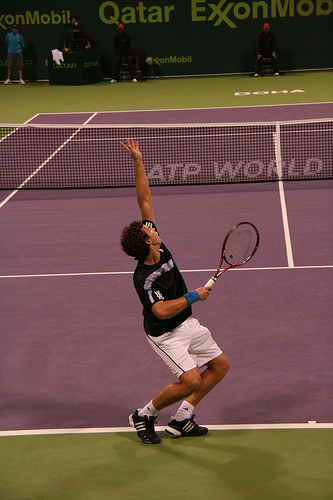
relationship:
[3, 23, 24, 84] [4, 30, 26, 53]
man in shirt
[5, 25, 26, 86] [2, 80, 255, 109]
man on sideline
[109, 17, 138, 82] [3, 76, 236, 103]
man on sideline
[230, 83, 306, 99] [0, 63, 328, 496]
sign on floor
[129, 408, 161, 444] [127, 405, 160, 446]
foot on foot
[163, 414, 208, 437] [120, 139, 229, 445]
shoe on man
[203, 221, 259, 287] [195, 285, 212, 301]
racket in hand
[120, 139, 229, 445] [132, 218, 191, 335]
man wearing shirt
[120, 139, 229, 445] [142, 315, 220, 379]
man wearing shorts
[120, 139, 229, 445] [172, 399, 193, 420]
man wearing sock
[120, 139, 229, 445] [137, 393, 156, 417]
man wearing sock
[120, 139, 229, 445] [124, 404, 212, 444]
man wearing shoes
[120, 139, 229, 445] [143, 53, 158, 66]
man hitting ball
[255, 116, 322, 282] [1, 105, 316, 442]
line on court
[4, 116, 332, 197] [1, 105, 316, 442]
net on court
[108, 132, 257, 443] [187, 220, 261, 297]
man holding racket